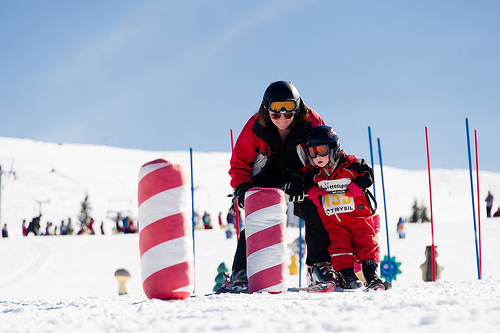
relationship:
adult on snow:
[228, 78, 348, 294] [435, 169, 475, 266]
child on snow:
[298, 119, 403, 306] [435, 169, 475, 266]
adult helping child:
[219, 78, 348, 294] [288, 123, 390, 291]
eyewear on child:
[309, 145, 331, 157] [296, 125, 391, 292]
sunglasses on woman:
[261, 103, 318, 125] [208, 83, 410, 260]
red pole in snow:
[427, 126, 437, 282] [12, 234, 485, 323]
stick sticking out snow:
[458, 114, 483, 279] [2, 137, 497, 331]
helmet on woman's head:
[256, 77, 303, 105] [253, 78, 308, 134]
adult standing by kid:
[228, 78, 348, 294] [296, 124, 386, 292]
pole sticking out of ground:
[373, 137, 399, 282] [6, 260, 488, 332]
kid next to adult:
[296, 124, 386, 292] [221, 81, 371, 293]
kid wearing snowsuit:
[296, 132, 386, 295] [316, 168, 380, 263]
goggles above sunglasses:
[268, 97, 296, 113] [270, 110, 297, 119]